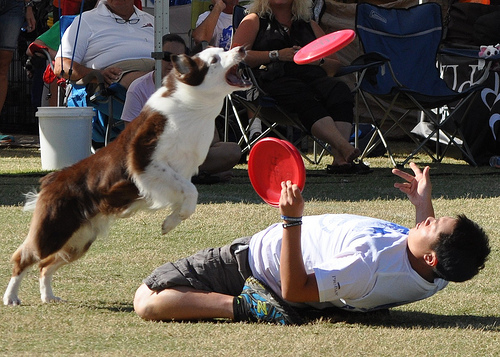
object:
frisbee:
[291, 28, 357, 66]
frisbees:
[245, 136, 308, 210]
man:
[131, 161, 493, 327]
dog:
[0, 45, 255, 308]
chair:
[352, 3, 483, 170]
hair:
[428, 212, 492, 283]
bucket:
[35, 106, 98, 170]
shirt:
[248, 211, 448, 314]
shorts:
[144, 236, 253, 297]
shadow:
[319, 307, 500, 331]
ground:
[0, 329, 500, 357]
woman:
[229, 0, 364, 173]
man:
[52, 1, 161, 92]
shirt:
[248, 10, 328, 85]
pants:
[257, 60, 356, 136]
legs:
[257, 77, 362, 163]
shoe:
[239, 274, 305, 327]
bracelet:
[282, 221, 302, 229]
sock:
[232, 295, 250, 325]